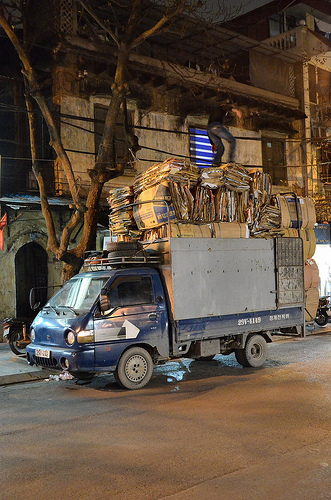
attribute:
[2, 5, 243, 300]
tree — bare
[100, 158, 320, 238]
boxes — tied-up, cardboard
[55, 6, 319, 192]
building — rock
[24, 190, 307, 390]
truck — parked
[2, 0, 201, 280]
tree — large, dead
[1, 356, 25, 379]
sidewalk — grey, concrete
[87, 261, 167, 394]
door — closed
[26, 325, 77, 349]
headlights — off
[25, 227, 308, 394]
truck — blue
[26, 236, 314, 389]
truck — blue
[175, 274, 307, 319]
truck bed — gray